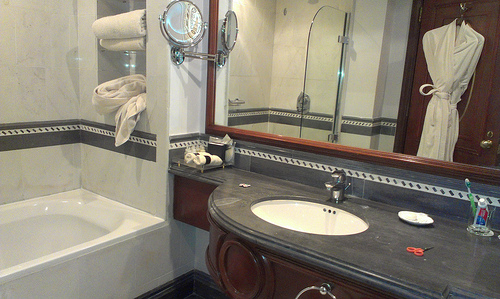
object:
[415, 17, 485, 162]
robe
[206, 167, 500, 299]
counter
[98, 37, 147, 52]
towel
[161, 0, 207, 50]
mirror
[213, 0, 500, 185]
mirror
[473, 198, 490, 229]
toothpaste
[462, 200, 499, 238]
glass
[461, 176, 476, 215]
brush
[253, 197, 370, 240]
sink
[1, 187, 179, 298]
tub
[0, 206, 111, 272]
water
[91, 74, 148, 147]
towel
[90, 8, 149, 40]
towel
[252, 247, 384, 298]
drawers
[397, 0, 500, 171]
door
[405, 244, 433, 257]
scissors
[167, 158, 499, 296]
countertop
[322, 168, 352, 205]
faucet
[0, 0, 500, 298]
bathroom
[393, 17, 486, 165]
hanger